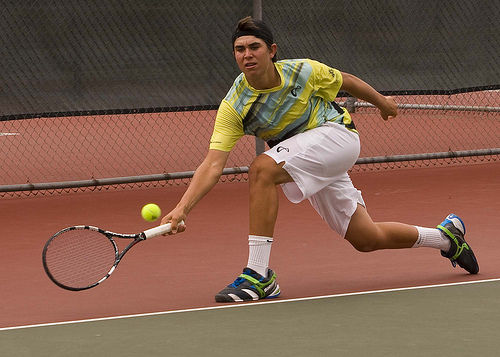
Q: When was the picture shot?
A: Daytime.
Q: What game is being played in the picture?
A: Tennis.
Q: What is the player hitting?
A: Tennis ball.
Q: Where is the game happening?
A: Tennis court.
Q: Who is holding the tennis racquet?
A: Tennis player.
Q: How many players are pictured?
A: One.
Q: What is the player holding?
A: Racquet.